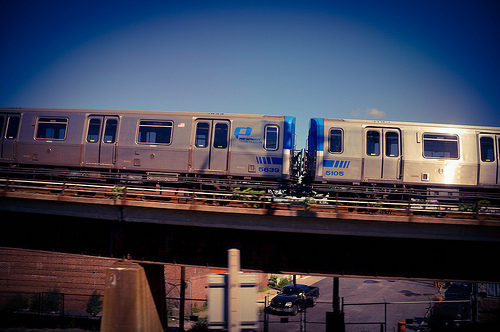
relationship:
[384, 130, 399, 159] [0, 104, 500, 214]
window on train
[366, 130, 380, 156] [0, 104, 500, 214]
window on train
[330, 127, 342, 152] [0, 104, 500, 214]
window on train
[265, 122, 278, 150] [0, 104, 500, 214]
window on train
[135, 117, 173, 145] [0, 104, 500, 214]
window on train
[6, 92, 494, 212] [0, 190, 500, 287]
train on bridge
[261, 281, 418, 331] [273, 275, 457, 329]
truck on roadway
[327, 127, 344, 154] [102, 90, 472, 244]
window on train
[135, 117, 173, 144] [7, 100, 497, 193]
window on train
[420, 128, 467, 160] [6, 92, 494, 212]
window of train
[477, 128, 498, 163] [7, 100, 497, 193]
window of train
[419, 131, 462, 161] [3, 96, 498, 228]
window of train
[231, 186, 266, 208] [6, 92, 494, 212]
shrubs near train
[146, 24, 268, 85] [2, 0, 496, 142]
cloud in sky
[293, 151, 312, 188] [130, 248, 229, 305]
shrubs next to building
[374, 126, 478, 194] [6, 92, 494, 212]
sun against train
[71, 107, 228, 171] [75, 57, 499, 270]
doors on train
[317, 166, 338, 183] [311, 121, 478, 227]
number on train